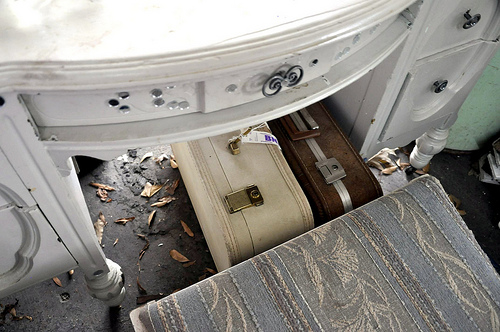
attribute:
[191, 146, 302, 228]
suitcase — white, khaki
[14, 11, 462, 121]
vanity table — antique, painted, white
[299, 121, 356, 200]
suitcase — brown, dark brown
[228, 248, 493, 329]
bench — blue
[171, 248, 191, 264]
leaf — brown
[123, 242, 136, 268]
floor — black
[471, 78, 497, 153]
wall — green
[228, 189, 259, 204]
latch — brass